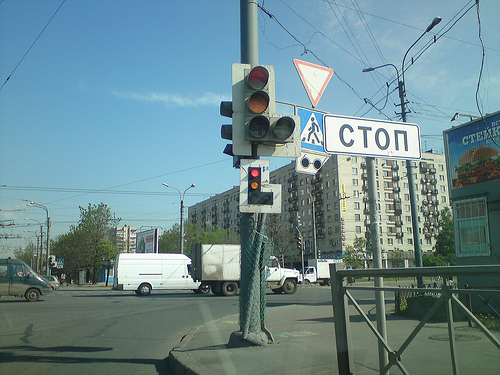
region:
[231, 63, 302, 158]
A stop light in public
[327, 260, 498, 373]
A metal gate on a side walk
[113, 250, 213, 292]
A white van on a road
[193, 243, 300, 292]
A box truck driving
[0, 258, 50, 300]
A green van driving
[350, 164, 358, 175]
A window on a building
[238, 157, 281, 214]
A stop light on a pole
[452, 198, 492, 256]
A sign up on a wall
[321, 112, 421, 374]
A street sign on a pole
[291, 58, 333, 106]
a red and white yield sign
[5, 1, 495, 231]
crossing wires against blue sky with few clouds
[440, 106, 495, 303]
large hamburger sign over grey building with bars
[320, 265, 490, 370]
sign behind metal railing on side of curb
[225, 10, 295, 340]
broken traffic signals over poster of red light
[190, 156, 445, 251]
wide gray building with small black terraces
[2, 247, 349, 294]
line of vehicles crossing paved street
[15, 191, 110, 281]
line of lampposts across from line of trees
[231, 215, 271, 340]
wire fencing wrapped around two poles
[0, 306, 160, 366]
shadows and stains on street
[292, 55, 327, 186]
vertical display of triangle, walker and sunglasses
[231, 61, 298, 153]
unlit traffic light on pole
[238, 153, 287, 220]
minature lit up traffic light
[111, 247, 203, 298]
white mini van on road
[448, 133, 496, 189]
hamburger advertisment on side of building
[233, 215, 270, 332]
green wire wrapped around light pole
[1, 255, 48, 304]
green and tan mini van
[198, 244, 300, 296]
white box truck on road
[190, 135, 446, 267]
large tan building with balconies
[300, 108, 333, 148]
blue and white sign with pedestrian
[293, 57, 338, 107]
red and white caution sign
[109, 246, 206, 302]
A van is on a street.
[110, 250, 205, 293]
The colors of a van are white and black.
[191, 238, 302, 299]
A truck is on a street.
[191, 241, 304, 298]
The colors of a truck are white, gray, and black.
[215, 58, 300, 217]
Several traffic lights are attached to a pole.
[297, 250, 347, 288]
A truck is in the background.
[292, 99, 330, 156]
A small sign's colors are blue and white.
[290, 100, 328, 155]
A walking sign is attached to a post.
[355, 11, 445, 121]
Two streetlights are visible.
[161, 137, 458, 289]
A tan building is in the background.